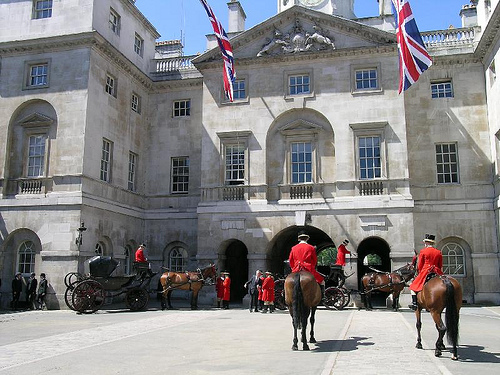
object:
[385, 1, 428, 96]
flag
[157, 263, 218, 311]
horse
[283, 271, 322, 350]
horse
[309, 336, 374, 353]
shadow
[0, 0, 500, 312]
building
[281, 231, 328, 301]
man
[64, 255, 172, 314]
carriage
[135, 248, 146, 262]
shirt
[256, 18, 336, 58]
figure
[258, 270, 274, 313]
person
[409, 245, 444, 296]
uniform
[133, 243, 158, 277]
man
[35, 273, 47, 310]
person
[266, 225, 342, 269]
arch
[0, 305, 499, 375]
pavement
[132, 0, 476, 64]
sky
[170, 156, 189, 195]
window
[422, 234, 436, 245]
hat